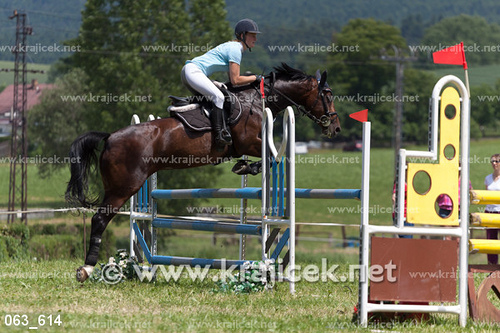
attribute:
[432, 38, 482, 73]
flag — orange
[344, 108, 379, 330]
pole — white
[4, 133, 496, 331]
grass — green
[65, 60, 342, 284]
horse — brown, dark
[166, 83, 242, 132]
saddle — english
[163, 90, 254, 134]
saddle — english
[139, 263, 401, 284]
letters — white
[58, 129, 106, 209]
tail — long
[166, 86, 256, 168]
english — black